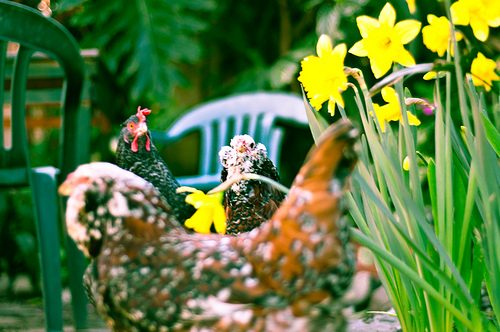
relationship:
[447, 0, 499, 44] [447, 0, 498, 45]
bloom of bloom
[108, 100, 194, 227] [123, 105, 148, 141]
chicken has head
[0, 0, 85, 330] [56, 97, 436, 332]
chair by chicken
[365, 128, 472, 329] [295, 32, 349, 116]
green stems on bloom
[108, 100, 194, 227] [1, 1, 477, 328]
chicken in garden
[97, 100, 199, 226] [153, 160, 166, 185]
chicken has feathers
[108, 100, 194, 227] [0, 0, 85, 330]
chicken beside chair